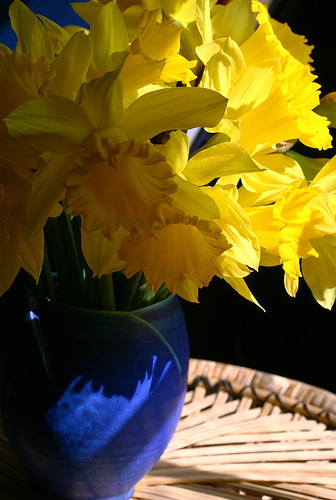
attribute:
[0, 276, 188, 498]
vase — blue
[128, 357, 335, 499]
table — brown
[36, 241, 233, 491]
vase — blue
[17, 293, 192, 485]
vase — OF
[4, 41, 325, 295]
flowers — IN